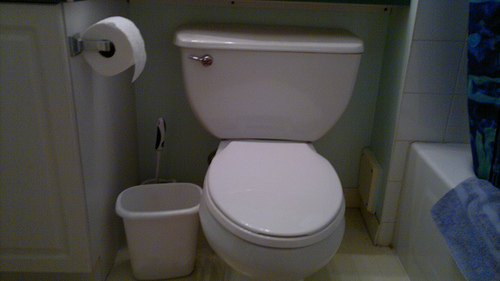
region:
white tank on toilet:
[189, 46, 359, 150]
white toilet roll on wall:
[64, 19, 151, 81]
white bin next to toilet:
[131, 185, 203, 250]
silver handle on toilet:
[178, 48, 229, 96]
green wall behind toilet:
[299, 13, 368, 28]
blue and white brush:
[158, 120, 181, 191]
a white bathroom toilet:
[168, 23, 388, 276]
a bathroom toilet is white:
[172, 10, 427, 241]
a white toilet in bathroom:
[166, 21, 351, 279]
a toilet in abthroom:
[166, 25, 408, 274]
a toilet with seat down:
[189, 31, 392, 245]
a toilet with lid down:
[169, 44, 436, 269]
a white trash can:
[103, 170, 239, 277]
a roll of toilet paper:
[74, 8, 145, 84]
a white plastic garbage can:
[119, 185, 201, 279]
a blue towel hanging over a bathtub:
[433, 165, 498, 279]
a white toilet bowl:
[183, 15, 373, 266]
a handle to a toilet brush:
[143, 112, 174, 182]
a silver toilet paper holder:
[67, 12, 107, 69]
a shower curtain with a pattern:
[466, 21, 498, 192]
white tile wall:
[400, 6, 453, 144]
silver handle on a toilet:
[185, 52, 215, 72]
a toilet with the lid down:
[193, 40, 363, 245]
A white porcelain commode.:
[171, 19, 368, 278]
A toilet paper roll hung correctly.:
[76, 14, 150, 87]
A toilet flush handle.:
[185, 49, 215, 70]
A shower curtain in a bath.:
[463, 2, 498, 191]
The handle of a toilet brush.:
[150, 114, 169, 185]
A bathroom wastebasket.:
[113, 178, 205, 278]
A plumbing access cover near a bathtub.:
[351, 143, 386, 215]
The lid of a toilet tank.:
[171, 17, 369, 55]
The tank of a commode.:
[169, 19, 365, 144]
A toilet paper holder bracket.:
[64, 30, 114, 59]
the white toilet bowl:
[173, 23, 365, 278]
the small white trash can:
[115, 180, 203, 276]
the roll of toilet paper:
[81, 13, 146, 82]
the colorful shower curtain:
[464, 2, 499, 189]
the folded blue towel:
[429, 175, 499, 280]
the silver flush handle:
[188, 50, 213, 68]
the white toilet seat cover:
[208, 137, 344, 237]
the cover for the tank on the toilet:
[171, 23, 364, 140]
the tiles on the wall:
[380, 0, 472, 247]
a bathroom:
[13, 3, 497, 275]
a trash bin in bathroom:
[110, 179, 204, 279]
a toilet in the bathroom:
[168, 17, 370, 278]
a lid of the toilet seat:
[199, 138, 347, 242]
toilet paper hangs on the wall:
[67, 15, 147, 82]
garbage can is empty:
[112, 180, 207, 277]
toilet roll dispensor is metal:
[64, 28, 113, 63]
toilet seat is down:
[202, 135, 346, 249]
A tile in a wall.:
[396, 88, 451, 145]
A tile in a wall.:
[380, 176, 405, 218]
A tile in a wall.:
[375, 220, 391, 242]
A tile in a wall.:
[401, 31, 460, 96]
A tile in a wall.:
[403, 5, 471, 46]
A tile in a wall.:
[454, 45, 481, 88]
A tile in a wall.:
[441, 90, 477, 152]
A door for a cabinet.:
[3, 7, 107, 272]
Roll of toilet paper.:
[68, 6, 170, 106]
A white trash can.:
[108, 166, 227, 277]